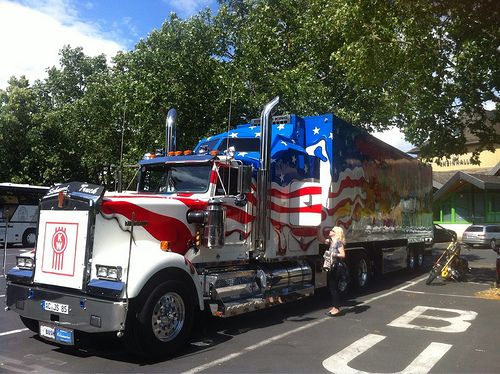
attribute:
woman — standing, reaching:
[324, 224, 346, 321]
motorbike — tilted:
[429, 236, 471, 283]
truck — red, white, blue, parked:
[6, 87, 286, 350]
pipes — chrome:
[163, 95, 283, 251]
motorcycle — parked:
[427, 230, 474, 281]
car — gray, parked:
[462, 221, 498, 250]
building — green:
[402, 107, 499, 246]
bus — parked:
[0, 172, 42, 249]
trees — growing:
[1, 0, 499, 178]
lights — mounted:
[149, 148, 227, 156]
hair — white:
[333, 227, 345, 249]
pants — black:
[324, 266, 342, 308]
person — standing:
[328, 224, 345, 317]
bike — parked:
[430, 235, 469, 286]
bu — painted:
[320, 307, 478, 373]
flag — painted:
[100, 114, 355, 242]